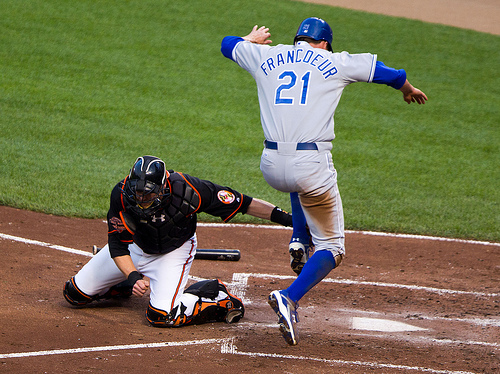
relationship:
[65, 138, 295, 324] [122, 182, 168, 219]
catcher wearing mask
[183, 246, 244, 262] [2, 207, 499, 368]
bat laying in dirt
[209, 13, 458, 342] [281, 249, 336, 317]
man wearing socks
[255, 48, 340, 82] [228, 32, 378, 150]
name on jersey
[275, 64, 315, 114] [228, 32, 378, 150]
number on jersey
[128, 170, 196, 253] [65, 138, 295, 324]
chest protector on player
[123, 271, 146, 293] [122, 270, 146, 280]
wristband on wrist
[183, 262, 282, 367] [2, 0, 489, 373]
lines on field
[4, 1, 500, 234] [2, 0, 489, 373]
grass on field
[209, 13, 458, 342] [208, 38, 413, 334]
player in uniform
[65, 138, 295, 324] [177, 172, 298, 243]
catcher with arm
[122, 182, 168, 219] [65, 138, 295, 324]
mask of catcher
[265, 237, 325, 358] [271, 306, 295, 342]
footwear with cleats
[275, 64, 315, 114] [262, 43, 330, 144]
number on back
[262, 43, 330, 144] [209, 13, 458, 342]
back of player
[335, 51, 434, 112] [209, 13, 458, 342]
arm of player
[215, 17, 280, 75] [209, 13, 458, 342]
arm of player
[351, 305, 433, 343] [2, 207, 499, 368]
home plate embedded in dirt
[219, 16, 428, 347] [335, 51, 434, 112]
man with arm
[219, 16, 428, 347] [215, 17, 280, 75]
man with arm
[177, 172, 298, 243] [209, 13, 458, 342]
arm in front of runner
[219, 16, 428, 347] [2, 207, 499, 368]
man on dirt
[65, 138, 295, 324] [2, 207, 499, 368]
player on dirt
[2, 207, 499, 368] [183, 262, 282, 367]
dirt with lines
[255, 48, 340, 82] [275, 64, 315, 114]
name over number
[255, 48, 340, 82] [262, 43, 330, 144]
name on back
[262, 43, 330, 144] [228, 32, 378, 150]
back of shirt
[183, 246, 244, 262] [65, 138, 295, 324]
bat behind catcher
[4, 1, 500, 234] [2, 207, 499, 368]
grass behind area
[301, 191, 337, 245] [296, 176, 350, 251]
dirt on thigh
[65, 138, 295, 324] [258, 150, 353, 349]
catcher between legs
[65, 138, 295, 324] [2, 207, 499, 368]
catcher looking at dirt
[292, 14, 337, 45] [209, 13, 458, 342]
helmet on batter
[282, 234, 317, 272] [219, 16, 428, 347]
shoe of man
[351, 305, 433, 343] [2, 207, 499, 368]
plate on ground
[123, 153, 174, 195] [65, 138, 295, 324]
helmet on catcher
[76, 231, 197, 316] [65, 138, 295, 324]
pants of catcher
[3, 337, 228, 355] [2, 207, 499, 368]
line on ground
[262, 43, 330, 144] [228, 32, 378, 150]
back of jersey